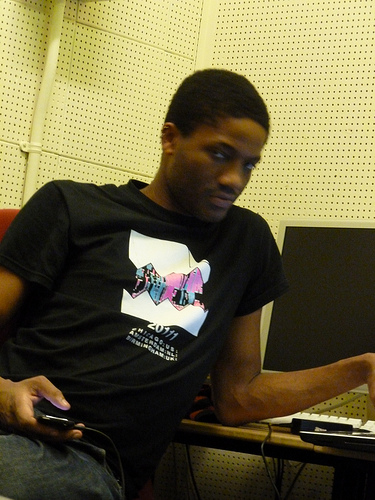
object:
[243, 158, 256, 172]
eyes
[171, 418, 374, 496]
computer desk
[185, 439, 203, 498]
cords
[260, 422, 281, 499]
cords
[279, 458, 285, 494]
cords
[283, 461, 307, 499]
cords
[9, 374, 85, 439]
hand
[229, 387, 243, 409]
veins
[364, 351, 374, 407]
hand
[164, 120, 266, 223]
face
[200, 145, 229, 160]
eye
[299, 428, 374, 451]
stuff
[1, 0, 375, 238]
white pegboard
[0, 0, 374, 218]
divider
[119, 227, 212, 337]
design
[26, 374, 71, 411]
thumb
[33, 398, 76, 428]
cellphone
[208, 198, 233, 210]
lip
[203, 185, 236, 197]
mustache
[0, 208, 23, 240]
chair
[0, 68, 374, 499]
guy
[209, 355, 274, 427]
elbow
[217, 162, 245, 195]
nose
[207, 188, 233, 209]
mouth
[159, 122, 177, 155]
ear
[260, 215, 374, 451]
laptop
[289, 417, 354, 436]
electrical connection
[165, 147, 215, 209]
cheek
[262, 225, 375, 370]
screen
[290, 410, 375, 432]
keyboard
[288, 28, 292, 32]
holes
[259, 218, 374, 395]
monitor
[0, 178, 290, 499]
shirt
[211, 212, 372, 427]
arm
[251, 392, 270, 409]
veins